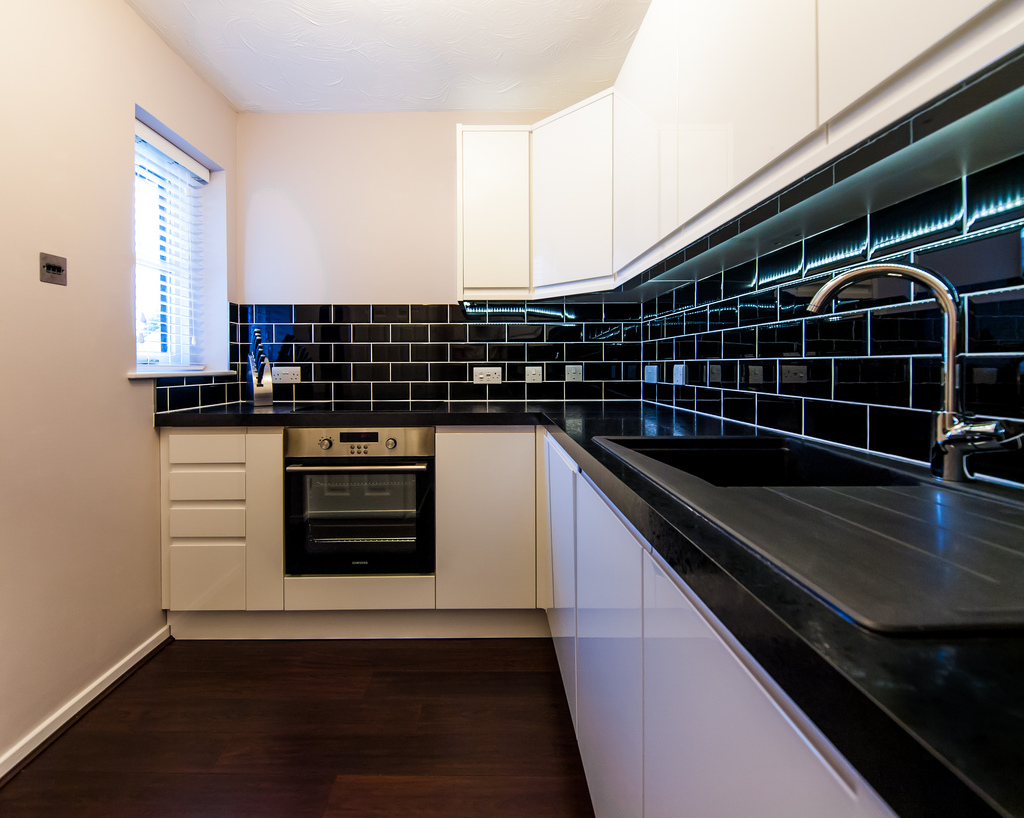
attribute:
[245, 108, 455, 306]
wall — small, white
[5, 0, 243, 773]
wall — large, white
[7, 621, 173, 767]
floor board — white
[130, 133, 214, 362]
window — white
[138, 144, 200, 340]
blinds — white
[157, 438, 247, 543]
drawer — white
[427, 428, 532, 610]
cabinet — white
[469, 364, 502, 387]
outlet — white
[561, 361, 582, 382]
tile — white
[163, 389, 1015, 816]
counter — black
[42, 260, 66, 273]
switches — black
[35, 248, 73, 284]
switch plate — silver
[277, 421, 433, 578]
oven — small, modern, built in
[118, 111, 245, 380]
window — small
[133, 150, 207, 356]
blinds — white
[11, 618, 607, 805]
flooring — dark brown, wood laminate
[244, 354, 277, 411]
holder — stainless steel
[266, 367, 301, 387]
socket — white, double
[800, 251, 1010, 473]
faucet — modern, stainless steel, kitchen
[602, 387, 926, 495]
sink — black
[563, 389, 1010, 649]
surround — gray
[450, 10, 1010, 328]
cabinets — white, plain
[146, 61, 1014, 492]
backsplash — black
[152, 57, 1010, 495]
grout — white